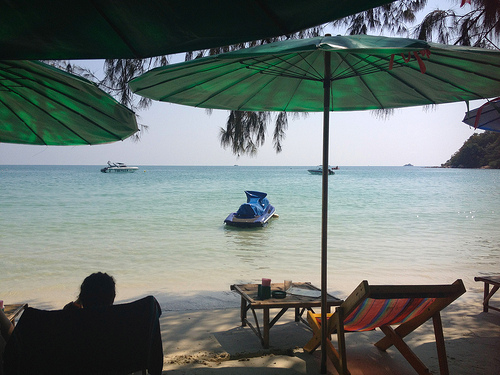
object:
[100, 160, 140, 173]
boat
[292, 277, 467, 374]
chair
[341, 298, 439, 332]
fabric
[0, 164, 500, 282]
ocean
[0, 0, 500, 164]
sky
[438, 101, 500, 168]
cliff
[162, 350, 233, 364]
green grass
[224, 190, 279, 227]
boat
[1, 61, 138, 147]
umbrella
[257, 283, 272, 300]
cup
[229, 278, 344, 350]
table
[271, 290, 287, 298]
items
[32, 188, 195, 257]
wave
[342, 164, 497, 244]
waves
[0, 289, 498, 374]
beach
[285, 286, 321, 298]
paper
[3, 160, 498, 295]
water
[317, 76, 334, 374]
pole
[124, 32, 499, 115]
umbrella